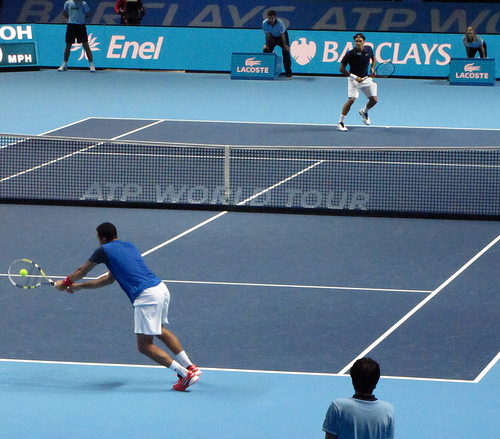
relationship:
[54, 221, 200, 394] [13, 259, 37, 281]
player plunging ball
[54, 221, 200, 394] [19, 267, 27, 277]
player lunging for ball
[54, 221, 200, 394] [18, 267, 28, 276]
player lunging for ball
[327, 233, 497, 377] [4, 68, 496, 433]
line on a court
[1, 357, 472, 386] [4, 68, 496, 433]
line on a court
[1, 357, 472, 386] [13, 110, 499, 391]
line on court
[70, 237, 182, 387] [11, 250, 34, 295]
player plunging ball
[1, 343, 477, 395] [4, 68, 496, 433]
line on a court